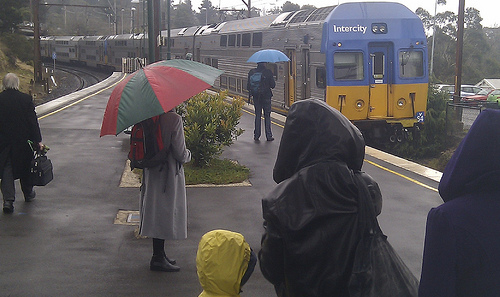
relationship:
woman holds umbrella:
[99, 52, 226, 136] [126, 113, 188, 271]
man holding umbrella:
[246, 58, 276, 142] [247, 48, 292, 68]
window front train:
[334, 55, 367, 82] [77, 15, 440, 115]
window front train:
[398, 52, 425, 77] [77, 15, 440, 115]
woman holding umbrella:
[123, 97, 199, 274] [98, 58, 223, 135]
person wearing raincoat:
[264, 104, 419, 295] [257, 96, 383, 295]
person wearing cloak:
[414, 100, 484, 292] [417, 105, 499, 295]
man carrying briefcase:
[0, 67, 50, 213] [30, 149, 55, 186]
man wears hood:
[246, 58, 276, 142] [182, 227, 262, 294]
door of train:
[288, 55, 300, 105] [197, 0, 442, 126]